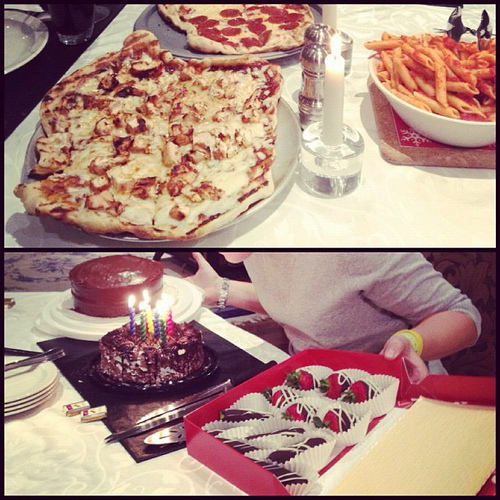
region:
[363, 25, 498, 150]
White bowl of pasta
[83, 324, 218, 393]
Cake on black tray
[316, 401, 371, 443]
Strawberry in white paper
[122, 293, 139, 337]
Purple candle on cake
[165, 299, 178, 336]
Pink candle on cake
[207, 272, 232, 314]
Watch on woman's wrist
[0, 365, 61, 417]
Stack of white plates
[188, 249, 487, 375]
Woman wearing gray shirt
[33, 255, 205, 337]
Chocolate covered cake on white platter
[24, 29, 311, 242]
Pizza on white plate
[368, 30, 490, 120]
fries in a bowl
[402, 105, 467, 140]
white bowl surrounding fries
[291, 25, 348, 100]
items next to bowl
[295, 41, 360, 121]
lit candle in photo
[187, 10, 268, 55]
toppings on the pizza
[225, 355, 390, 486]
food in a red case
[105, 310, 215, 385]
cake on the table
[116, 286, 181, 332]
candles on the cake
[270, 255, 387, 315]
gray shirt on person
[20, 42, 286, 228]
pizza on white plate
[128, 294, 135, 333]
A lit birthday candle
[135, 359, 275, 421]
A knife on a table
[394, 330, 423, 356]
Wristband worn on left hand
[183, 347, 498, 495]
A red box of cupcakes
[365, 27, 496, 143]
A bowl of pasta noodles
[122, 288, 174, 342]
Candles lit next to each other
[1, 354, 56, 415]
White dinner plates on a table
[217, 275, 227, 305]
A worn wrist accessory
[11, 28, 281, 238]
Freshly cooked pizza on a plate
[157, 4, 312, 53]
Pepperoni pizza that was cooked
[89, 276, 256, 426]
a brown cake with candles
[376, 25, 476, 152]
pasta in a bowl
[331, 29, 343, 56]
White flame on a candle.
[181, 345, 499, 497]
Red plastic container full of chocolate covered strawberries and something else.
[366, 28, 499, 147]
White oblong dish with pasta in it.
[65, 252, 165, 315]
A chocolate round cake with no candles.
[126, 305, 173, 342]
All the colored candles on a chocolate cake.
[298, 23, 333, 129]
Silver salt and pepper shakers.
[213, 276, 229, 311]
Bracelet on the right wrist of a woman.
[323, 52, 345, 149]
A white candle.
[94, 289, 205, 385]
A round chocolate cake with lit candles.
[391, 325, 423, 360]
Yellow bracelets on the left wrist of a woman.